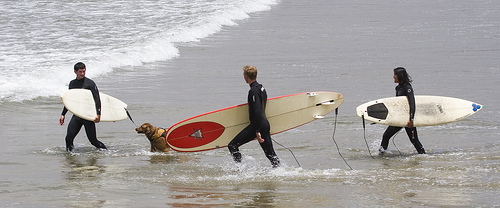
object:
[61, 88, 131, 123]
surfboards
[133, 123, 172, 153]
dog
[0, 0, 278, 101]
wave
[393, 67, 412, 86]
hair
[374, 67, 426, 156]
woman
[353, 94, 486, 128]
surboard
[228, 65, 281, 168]
man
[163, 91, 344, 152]
surfboard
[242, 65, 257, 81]
hair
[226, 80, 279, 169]
wetsuit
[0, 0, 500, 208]
ocean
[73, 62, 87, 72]
hair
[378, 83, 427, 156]
wetsuit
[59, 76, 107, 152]
wetsuit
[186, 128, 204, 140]
logo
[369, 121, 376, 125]
fin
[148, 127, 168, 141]
harness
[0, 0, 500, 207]
beach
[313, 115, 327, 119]
fins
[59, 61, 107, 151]
surfer